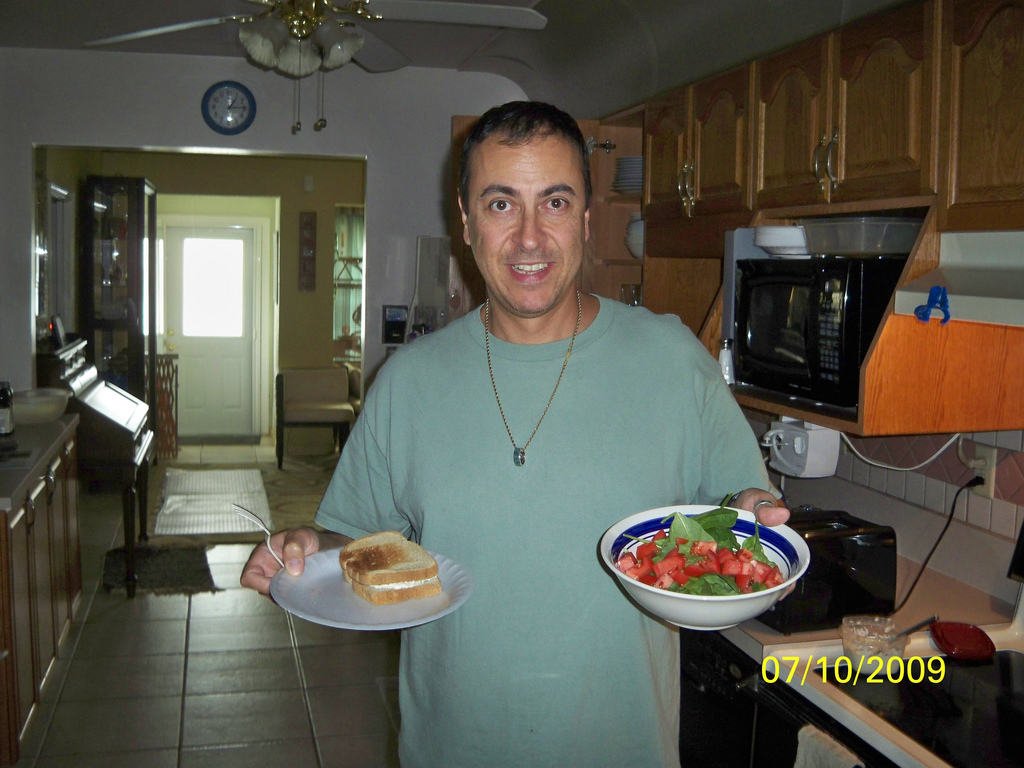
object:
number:
[782, 656, 800, 683]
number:
[816, 656, 826, 683]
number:
[887, 656, 905, 684]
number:
[907, 655, 925, 683]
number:
[928, 656, 946, 684]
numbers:
[762, 656, 799, 684]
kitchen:
[0, 0, 1023, 767]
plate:
[269, 547, 474, 630]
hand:
[239, 526, 336, 606]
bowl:
[600, 504, 810, 632]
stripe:
[611, 514, 800, 579]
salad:
[613, 492, 784, 596]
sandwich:
[339, 530, 442, 606]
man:
[239, 101, 792, 767]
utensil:
[231, 504, 285, 568]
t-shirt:
[314, 294, 781, 767]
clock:
[201, 80, 258, 136]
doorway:
[30, 142, 370, 549]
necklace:
[484, 290, 583, 466]